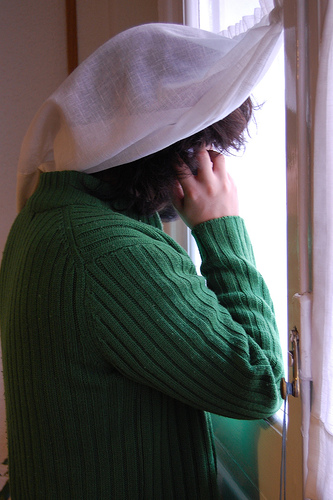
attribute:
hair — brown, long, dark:
[96, 155, 189, 213]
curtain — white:
[19, 25, 274, 171]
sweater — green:
[0, 214, 280, 454]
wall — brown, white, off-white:
[2, 1, 67, 81]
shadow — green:
[216, 417, 254, 480]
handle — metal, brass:
[278, 330, 300, 406]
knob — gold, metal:
[277, 379, 290, 400]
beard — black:
[158, 202, 176, 227]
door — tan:
[283, 1, 316, 499]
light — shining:
[262, 45, 284, 272]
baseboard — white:
[218, 468, 248, 499]